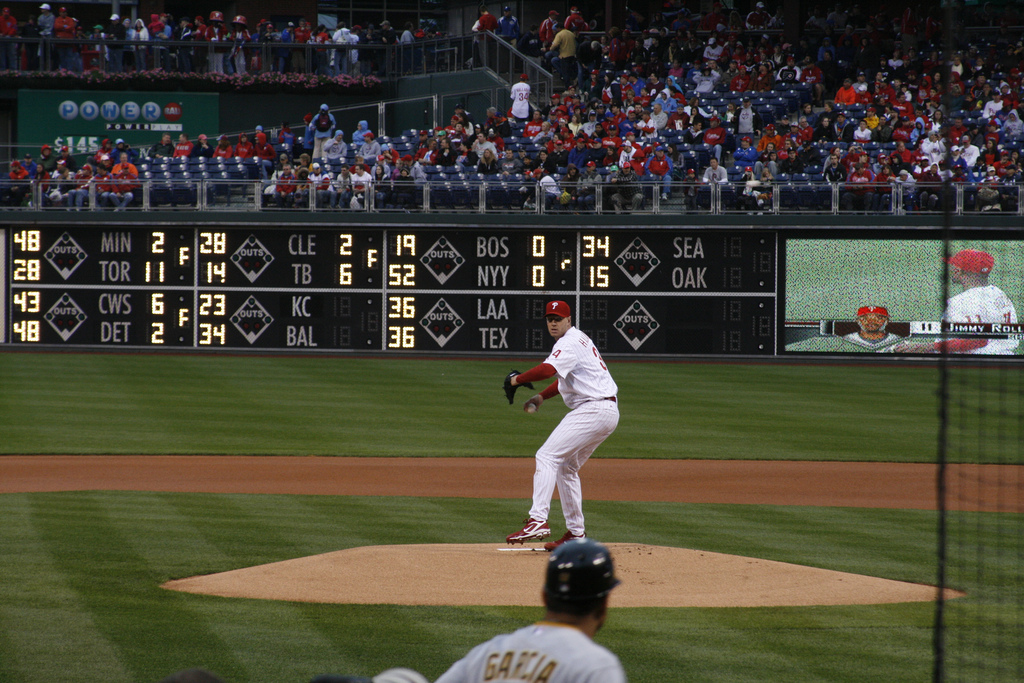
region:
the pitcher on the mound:
[488, 296, 628, 537]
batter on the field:
[394, 546, 652, 677]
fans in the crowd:
[289, 18, 1017, 208]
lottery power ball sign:
[68, 101, 182, 131]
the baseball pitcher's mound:
[191, 528, 828, 601]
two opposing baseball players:
[345, 279, 674, 679]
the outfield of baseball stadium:
[10, 341, 456, 463]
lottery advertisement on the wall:
[39, 89, 191, 144]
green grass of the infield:
[33, 499, 164, 655]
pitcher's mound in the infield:
[239, 538, 910, 614]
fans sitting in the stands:
[527, 88, 854, 212]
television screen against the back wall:
[785, 239, 1021, 361]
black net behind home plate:
[919, 23, 1021, 678]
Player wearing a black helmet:
[529, 526, 632, 643]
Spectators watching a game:
[0, 1, 1018, 210]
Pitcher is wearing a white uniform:
[494, 283, 627, 553]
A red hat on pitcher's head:
[529, 283, 580, 347]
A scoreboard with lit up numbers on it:
[0, 209, 784, 368]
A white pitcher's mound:
[478, 529, 554, 561]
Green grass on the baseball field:
[1, 337, 1016, 673]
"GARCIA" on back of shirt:
[472, 635, 569, 679]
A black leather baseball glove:
[488, 355, 549, 414]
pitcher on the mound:
[498, 290, 632, 550]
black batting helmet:
[525, 525, 636, 620]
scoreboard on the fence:
[8, 211, 776, 361]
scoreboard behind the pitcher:
[9, 217, 778, 370]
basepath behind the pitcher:
[3, 446, 1022, 514]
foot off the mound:
[503, 508, 552, 548]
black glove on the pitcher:
[496, 363, 536, 406]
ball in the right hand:
[521, 397, 541, 420]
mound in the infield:
[147, 518, 967, 624]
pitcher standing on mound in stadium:
[501, 300, 622, 551]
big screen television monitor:
[781, 233, 1022, 358]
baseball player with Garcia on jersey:
[431, 539, 634, 680]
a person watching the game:
[652, 116, 681, 154]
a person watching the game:
[819, 118, 857, 144]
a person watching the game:
[901, 101, 936, 147]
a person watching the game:
[412, 145, 455, 183]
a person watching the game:
[318, 168, 373, 203]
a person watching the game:
[631, 98, 660, 127]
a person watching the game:
[664, 77, 710, 126]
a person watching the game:
[705, 89, 751, 132]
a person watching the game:
[778, 42, 833, 132]